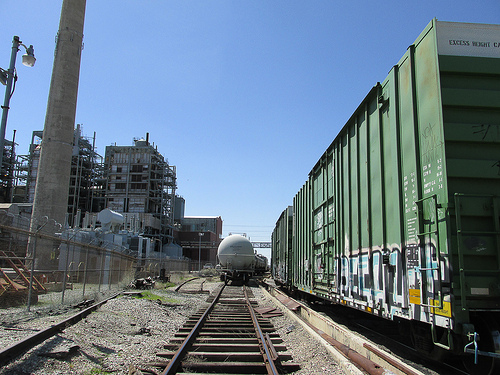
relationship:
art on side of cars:
[323, 240, 453, 328] [270, 18, 498, 373]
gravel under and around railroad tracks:
[101, 306, 150, 363] [140, 277, 301, 373]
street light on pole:
[15, 37, 37, 68] [4, 30, 24, 135]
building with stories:
[104, 129, 180, 231] [126, 153, 149, 214]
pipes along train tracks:
[11, 294, 118, 371] [146, 277, 302, 369]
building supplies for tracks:
[118, 266, 162, 296] [182, 287, 285, 372]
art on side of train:
[323, 239, 451, 324] [273, 17, 484, 360]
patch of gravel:
[45, 287, 176, 370] [94, 309, 127, 345]